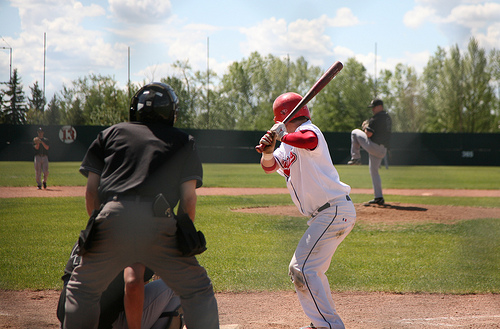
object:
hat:
[128, 81, 180, 126]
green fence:
[0, 124, 500, 168]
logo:
[58, 125, 77, 144]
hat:
[367, 99, 384, 109]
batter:
[253, 61, 357, 329]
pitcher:
[347, 98, 393, 206]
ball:
[362, 119, 370, 130]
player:
[55, 82, 220, 329]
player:
[32, 127, 52, 190]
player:
[55, 225, 187, 329]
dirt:
[231, 201, 500, 226]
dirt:
[0, 286, 500, 329]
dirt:
[0, 184, 500, 224]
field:
[0, 159, 500, 329]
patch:
[391, 305, 426, 317]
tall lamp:
[157, 302, 188, 329]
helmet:
[266, 90, 313, 124]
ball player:
[255, 60, 357, 329]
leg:
[350, 127, 365, 157]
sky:
[0, 0, 500, 85]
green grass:
[0, 159, 500, 295]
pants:
[288, 200, 356, 329]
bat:
[254, 60, 346, 155]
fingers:
[260, 131, 273, 145]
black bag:
[347, 98, 394, 206]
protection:
[154, 311, 183, 329]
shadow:
[383, 202, 429, 211]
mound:
[223, 198, 500, 228]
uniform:
[351, 109, 393, 199]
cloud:
[0, 0, 500, 91]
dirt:
[335, 226, 345, 241]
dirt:
[287, 265, 310, 295]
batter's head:
[272, 91, 312, 133]